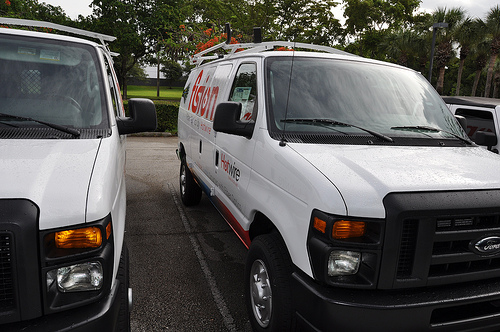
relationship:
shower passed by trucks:
[421, 4, 489, 29] [2, 47, 445, 290]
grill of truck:
[397, 202, 488, 255] [200, 38, 470, 307]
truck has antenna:
[200, 38, 470, 307] [277, 31, 297, 136]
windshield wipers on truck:
[283, 109, 436, 143] [200, 38, 470, 307]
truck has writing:
[200, 38, 470, 307] [185, 70, 232, 131]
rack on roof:
[200, 28, 333, 64] [188, 49, 403, 71]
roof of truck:
[188, 49, 403, 71] [200, 38, 470, 307]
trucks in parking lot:
[2, 47, 445, 290] [7, 115, 499, 286]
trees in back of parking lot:
[394, 6, 500, 71] [7, 115, 499, 286]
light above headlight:
[335, 216, 380, 242] [324, 247, 363, 277]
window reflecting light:
[266, 57, 468, 138] [344, 72, 425, 95]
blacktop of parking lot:
[135, 137, 172, 193] [7, 115, 499, 286]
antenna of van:
[277, 31, 297, 136] [172, 52, 465, 272]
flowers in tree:
[196, 20, 237, 50] [150, 2, 351, 117]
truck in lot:
[176, 23, 499, 330] [47, 37, 494, 243]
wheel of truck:
[247, 251, 280, 330] [176, 23, 499, 330]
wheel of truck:
[174, 164, 211, 213] [176, 23, 499, 330]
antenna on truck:
[277, 31, 297, 136] [176, 23, 499, 330]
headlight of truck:
[324, 247, 363, 277] [176, 23, 499, 330]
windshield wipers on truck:
[283, 109, 436, 143] [176, 23, 499, 330]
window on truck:
[266, 57, 468, 138] [176, 23, 499, 330]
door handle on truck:
[214, 151, 221, 178] [176, 23, 499, 330]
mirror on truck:
[209, 105, 263, 138] [176, 23, 499, 330]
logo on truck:
[476, 233, 499, 251] [176, 23, 499, 330]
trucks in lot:
[2, 47, 445, 290] [47, 37, 494, 243]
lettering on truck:
[189, 66, 229, 131] [200, 38, 470, 307]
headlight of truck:
[324, 247, 363, 277] [200, 38, 470, 307]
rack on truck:
[200, 28, 333, 64] [200, 38, 470, 307]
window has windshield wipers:
[266, 57, 447, 135] [283, 109, 436, 143]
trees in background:
[394, 6, 500, 71] [19, 2, 484, 120]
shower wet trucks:
[421, 4, 489, 29] [2, 47, 445, 290]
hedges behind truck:
[124, 101, 185, 129] [200, 38, 470, 307]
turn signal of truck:
[316, 217, 329, 235] [176, 23, 499, 330]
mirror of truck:
[209, 105, 263, 138] [176, 23, 499, 330]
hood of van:
[329, 151, 499, 183] [172, 52, 465, 272]